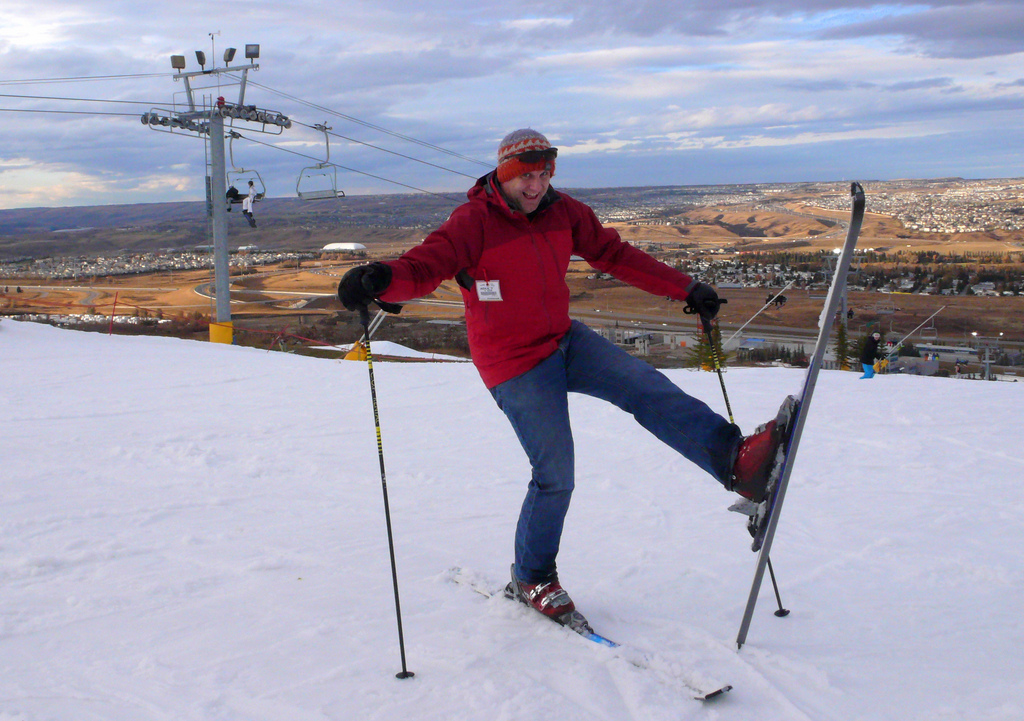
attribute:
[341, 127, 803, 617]
person — standing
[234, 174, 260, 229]
person — seated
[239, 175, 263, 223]
person — seated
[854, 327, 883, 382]
person — standing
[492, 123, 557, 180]
ski cap — red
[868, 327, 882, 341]
ski cap — red ski 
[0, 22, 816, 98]
clouds — white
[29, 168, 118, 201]
clouds — white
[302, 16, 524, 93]
clouds — white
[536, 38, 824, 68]
clouds — white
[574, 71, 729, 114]
clouds — white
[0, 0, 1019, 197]
sky — blue, Dark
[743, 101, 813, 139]
clouds — white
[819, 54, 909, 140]
clouds — white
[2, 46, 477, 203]
cables — Electric